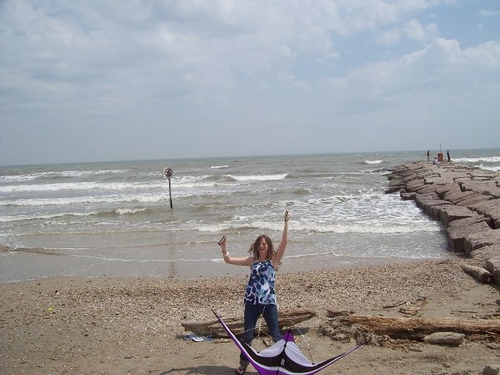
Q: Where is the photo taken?
A: Beach.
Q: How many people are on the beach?
A: One.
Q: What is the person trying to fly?
A: Kite.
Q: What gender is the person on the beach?
A: Female.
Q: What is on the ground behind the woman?
A: Rocks.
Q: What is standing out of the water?
A: Sign.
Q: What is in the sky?
A: Clouds.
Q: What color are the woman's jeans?
A: Blue.